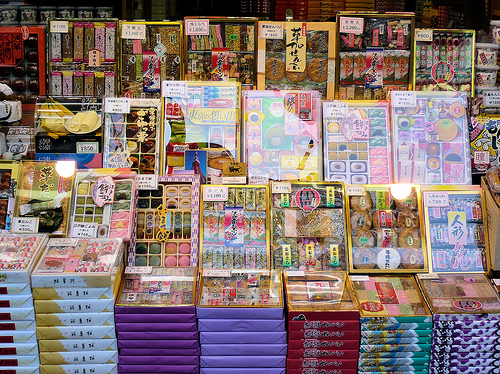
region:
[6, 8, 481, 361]
a magazine rack stand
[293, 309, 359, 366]
a red stack of books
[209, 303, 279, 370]
a purple stack of books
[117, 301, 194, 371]
a dark purple stack of books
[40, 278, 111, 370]
a white and gold stack of books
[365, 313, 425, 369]
a green and gray stack of books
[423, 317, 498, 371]
a white and black stack of books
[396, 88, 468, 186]
a magazine with circle all over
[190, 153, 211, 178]
a tower on a page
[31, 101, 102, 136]
yellow food on the cover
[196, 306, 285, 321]
Light purple wrapping paper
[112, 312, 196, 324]
Dark purple wrapping paper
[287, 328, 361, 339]
Red paper with black decorations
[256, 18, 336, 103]
Gift box with black writing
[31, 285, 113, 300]
Blue and gold wrapping paper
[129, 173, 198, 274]
Gift box with six different treats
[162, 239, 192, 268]
Pink treats in a gift box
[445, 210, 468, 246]
Yellow label with black writing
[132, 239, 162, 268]
Four green treats in a gift box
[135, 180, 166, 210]
Black treats in a gift box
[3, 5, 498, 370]
outdoor market stand selling baked goods in Asia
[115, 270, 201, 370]
stack of purple packages of baked goods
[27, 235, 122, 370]
stack of blue and gold packages of baked goods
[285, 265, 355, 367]
stack of red packages of baked goods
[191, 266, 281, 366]
stack of periwinkle blue packages of baked goods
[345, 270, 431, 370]
stack of green and gold baked goods packages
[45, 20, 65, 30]
price of baked goods on white card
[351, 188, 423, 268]
muffins in plastic in box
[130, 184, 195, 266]
green and pink sweets in box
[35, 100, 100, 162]
banana rolls in box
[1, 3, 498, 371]
Set of packages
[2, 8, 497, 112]
Packages on the top row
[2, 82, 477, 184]
Packages on the middle row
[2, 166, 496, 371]
Packages on the bottom row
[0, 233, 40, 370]
Stack of packages with a black and white cover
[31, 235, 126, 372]
Stack of packages with a white and golden cover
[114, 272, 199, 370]
stack of packages with a purple cover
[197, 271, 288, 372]
Stack of packages with a lavender cover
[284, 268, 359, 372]
Stack of packages with a red cover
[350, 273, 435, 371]
Stack of packages with a green cover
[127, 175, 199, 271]
a box of candies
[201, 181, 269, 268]
a box of candies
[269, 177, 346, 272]
a box of candies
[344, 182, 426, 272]
a box of candies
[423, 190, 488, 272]
a box of candies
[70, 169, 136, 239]
a box of candies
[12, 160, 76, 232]
a box of candies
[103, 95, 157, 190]
a box of candies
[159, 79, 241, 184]
a box of candies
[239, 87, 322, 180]
a box of candies